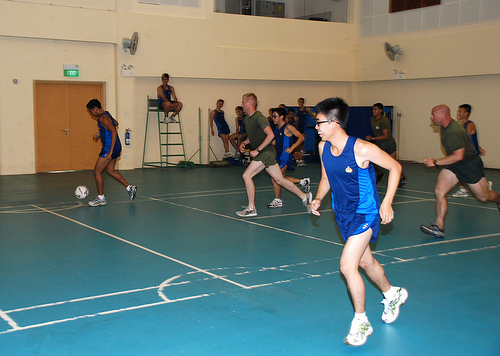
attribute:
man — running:
[305, 94, 404, 347]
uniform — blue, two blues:
[321, 144, 383, 242]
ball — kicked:
[71, 180, 93, 202]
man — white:
[422, 102, 499, 236]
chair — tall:
[139, 94, 190, 171]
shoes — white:
[343, 285, 416, 348]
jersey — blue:
[319, 139, 377, 214]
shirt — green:
[238, 115, 276, 145]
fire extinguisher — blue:
[121, 120, 134, 150]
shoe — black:
[421, 219, 445, 240]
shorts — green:
[247, 146, 280, 166]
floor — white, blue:
[0, 157, 484, 353]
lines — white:
[4, 183, 483, 333]